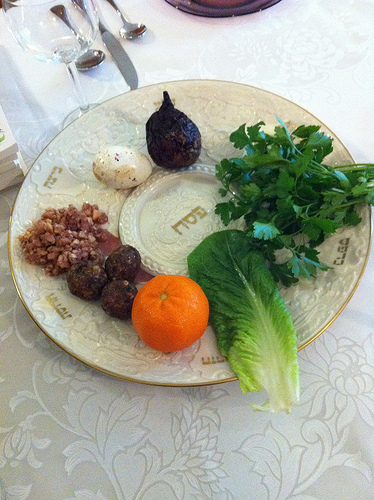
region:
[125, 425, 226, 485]
the cloth is designed by flower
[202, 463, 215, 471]
the cloth is designed by flower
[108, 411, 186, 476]
the cloth is designed by flower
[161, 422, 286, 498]
the cloth is designed by flower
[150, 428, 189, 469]
the cloth is designed by flower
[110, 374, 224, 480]
the cloth is designed by flower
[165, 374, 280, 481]
the cloth is designed by flower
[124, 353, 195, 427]
the cloth is designed by flower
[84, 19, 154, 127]
a knife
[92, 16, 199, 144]
a knife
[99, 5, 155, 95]
a knife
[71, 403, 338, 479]
white linen tablecloth with embossed floral design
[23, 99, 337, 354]
food on white dish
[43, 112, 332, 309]
healthy fruits and vegetables on white plate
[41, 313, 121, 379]
white plate with designs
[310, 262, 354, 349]
white plate with gold border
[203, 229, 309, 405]
piece of romaine letteuce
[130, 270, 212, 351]
small orange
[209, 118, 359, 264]
bunch of green parsley on plate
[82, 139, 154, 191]
boiled egg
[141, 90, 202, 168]
one fig on plate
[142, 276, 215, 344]
Bright orange on plate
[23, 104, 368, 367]
Round decorated plate on cloth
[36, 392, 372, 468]
White table cloth with floral pattern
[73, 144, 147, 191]
Single exotic egg on plate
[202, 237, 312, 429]
Large leaf garnishing plate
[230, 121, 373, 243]
Green leaves on plate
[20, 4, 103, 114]
Transparent wine glass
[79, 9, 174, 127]
Metal knife behind plate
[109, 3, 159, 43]
Metal spoon behind plate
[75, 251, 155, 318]
Three meat balls on plate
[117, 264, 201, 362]
orange on the plate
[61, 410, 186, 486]
flower design on the table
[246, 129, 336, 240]
green leaves on plate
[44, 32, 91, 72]
clear glass on table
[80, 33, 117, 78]
spoon next to the glass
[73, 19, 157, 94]
two spoons and a knife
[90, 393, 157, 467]
white leaf design on table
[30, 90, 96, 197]
round plate on table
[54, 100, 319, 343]
food on the plate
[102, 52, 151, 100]
knife on the table